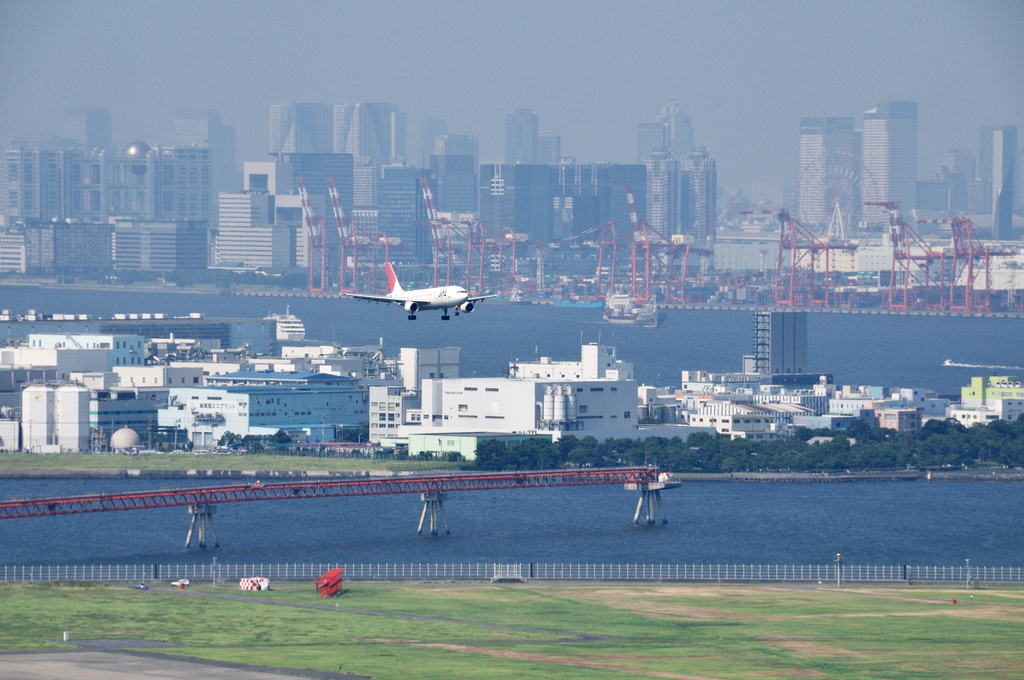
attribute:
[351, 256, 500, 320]
plane — white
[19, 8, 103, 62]
clouds — white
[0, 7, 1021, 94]
sky — blue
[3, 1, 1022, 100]
sky — blue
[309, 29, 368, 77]
clouds — white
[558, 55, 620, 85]
clouds — white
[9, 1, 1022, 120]
sky — blue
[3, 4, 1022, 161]
sky — blue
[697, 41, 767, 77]
clouds — white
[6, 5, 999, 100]
clouds — white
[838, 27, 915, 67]
sky — blue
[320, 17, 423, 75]
cloud — white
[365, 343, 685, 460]
building — white, large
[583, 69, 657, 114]
cloud — white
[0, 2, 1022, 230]
sky — blue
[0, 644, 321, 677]
road — black, paved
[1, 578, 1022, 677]
lawn — green, grassy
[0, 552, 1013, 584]
fence — silver, metal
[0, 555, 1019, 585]
fence — metal, silver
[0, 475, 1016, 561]
water — large, body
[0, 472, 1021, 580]
water — large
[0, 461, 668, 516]
bridge — red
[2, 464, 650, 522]
bridge — large, red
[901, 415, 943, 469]
leaves — green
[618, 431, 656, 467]
leaves — green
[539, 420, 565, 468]
leaves — green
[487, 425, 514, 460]
leaves — green